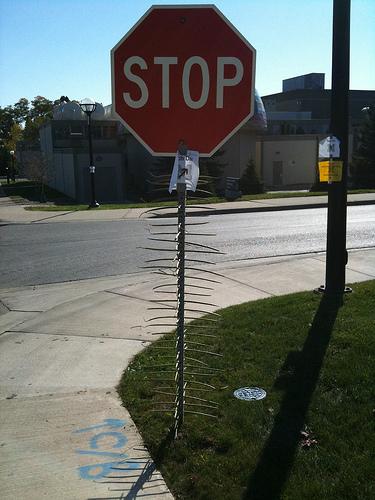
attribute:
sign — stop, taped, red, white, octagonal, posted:
[103, 6, 270, 145]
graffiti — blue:
[66, 407, 146, 499]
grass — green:
[217, 393, 323, 489]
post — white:
[124, 192, 216, 433]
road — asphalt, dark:
[35, 216, 115, 282]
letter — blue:
[78, 407, 158, 480]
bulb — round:
[74, 86, 102, 125]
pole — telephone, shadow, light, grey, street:
[310, 5, 366, 309]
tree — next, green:
[2, 85, 86, 181]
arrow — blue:
[81, 421, 142, 477]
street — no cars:
[23, 218, 143, 305]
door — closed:
[271, 144, 288, 191]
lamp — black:
[78, 79, 108, 250]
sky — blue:
[23, 12, 82, 81]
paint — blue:
[69, 386, 154, 495]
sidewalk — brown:
[234, 243, 293, 294]